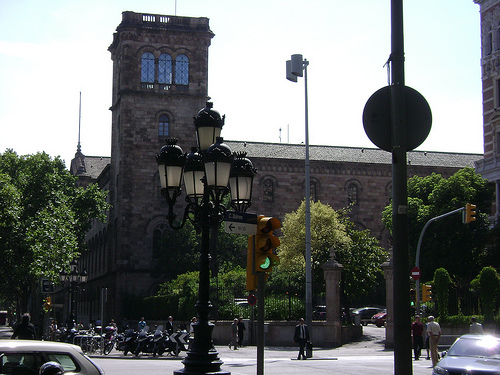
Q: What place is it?
A: It is a town.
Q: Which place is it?
A: It is a town.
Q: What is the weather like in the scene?
A: It is cloudy.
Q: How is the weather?
A: It is cloudy.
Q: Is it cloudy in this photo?
A: Yes, it is cloudy.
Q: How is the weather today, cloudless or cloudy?
A: It is cloudy.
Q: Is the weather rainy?
A: No, it is cloudy.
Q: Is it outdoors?
A: Yes, it is outdoors.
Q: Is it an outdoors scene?
A: Yes, it is outdoors.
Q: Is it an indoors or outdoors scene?
A: It is outdoors.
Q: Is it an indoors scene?
A: No, it is outdoors.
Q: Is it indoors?
A: No, it is outdoors.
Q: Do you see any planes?
A: No, there are no planes.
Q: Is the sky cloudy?
A: Yes, the sky is cloudy.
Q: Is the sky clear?
A: No, the sky is cloudy.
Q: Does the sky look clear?
A: No, the sky is cloudy.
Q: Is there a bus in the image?
A: No, there are no buses.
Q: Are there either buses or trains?
A: No, there are no buses or trains.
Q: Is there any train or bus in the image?
A: No, there are no buses or trains.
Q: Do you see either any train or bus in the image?
A: No, there are no buses or trains.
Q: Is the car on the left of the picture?
A: Yes, the car is on the left of the image.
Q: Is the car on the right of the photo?
A: No, the car is on the left of the image.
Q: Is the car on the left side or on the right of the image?
A: The car is on the left of the image.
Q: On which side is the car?
A: The car is on the left of the image.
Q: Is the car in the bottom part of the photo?
A: Yes, the car is in the bottom of the image.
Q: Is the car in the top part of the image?
A: No, the car is in the bottom of the image.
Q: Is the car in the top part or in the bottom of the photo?
A: The car is in the bottom of the image.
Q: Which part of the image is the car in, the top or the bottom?
A: The car is in the bottom of the image.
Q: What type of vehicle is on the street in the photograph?
A: The vehicle is a car.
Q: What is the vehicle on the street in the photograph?
A: The vehicle is a car.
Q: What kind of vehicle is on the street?
A: The vehicle is a car.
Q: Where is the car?
A: The car is on the street.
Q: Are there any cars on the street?
A: Yes, there is a car on the street.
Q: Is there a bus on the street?
A: No, there is a car on the street.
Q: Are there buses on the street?
A: No, there is a car on the street.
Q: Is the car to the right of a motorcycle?
A: No, the car is to the left of a motorcycle.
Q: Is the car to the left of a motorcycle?
A: Yes, the car is to the left of a motorcycle.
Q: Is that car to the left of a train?
A: No, the car is to the left of a motorcycle.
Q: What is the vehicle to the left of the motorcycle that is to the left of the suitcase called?
A: The vehicle is a car.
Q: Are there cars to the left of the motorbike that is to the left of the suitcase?
A: Yes, there is a car to the left of the motorbike.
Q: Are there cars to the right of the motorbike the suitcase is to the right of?
A: No, the car is to the left of the motorbike.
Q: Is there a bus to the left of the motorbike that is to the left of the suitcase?
A: No, there is a car to the left of the motorcycle.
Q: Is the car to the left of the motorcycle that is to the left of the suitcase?
A: Yes, the car is to the left of the motorbike.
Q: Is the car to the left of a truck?
A: No, the car is to the left of the motorbike.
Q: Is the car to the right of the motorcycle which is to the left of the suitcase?
A: No, the car is to the left of the motorbike.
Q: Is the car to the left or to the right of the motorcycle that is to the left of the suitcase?
A: The car is to the left of the motorbike.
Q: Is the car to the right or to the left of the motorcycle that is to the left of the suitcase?
A: The car is to the left of the motorbike.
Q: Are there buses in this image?
A: No, there are no buses.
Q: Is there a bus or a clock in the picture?
A: No, there are no buses or clocks.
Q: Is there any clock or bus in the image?
A: No, there are no buses or clocks.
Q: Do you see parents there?
A: No, there are no parents.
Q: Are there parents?
A: No, there are no parents.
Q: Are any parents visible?
A: No, there are no parents.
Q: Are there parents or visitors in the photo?
A: No, there are no parents or visitors.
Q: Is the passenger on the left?
A: Yes, the passenger is on the left of the image.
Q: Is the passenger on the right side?
A: No, the passenger is on the left of the image.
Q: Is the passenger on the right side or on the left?
A: The passenger is on the left of the image.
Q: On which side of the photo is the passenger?
A: The passenger is on the left of the image.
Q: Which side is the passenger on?
A: The passenger is on the left of the image.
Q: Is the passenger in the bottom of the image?
A: Yes, the passenger is in the bottom of the image.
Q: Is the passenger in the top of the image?
A: No, the passenger is in the bottom of the image.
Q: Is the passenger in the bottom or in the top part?
A: The passenger is in the bottom of the image.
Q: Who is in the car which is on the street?
A: The passenger is in the car.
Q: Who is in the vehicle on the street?
A: The passenger is in the car.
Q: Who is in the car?
A: The passenger is in the car.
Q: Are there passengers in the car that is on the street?
A: Yes, there is a passenger in the car.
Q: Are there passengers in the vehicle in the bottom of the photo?
A: Yes, there is a passenger in the car.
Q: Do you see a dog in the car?
A: No, there is a passenger in the car.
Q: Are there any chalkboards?
A: No, there are no chalkboards.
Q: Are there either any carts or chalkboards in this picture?
A: No, there are no chalkboards or carts.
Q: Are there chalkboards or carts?
A: No, there are no chalkboards or carts.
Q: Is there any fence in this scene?
A: Yes, there is a fence.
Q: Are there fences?
A: Yes, there is a fence.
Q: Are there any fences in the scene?
A: Yes, there is a fence.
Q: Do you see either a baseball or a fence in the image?
A: Yes, there is a fence.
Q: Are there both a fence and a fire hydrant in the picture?
A: No, there is a fence but no fire hydrants.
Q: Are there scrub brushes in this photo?
A: No, there are no scrub brushes.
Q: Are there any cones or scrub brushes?
A: No, there are no scrub brushes or cones.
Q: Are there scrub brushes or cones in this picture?
A: No, there are no scrub brushes or cones.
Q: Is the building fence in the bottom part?
A: Yes, the fence is in the bottom of the image.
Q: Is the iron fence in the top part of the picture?
A: No, the fence is in the bottom of the image.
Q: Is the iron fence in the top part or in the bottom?
A: The fence is in the bottom of the image.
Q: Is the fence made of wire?
A: No, the fence is made of iron.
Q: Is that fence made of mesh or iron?
A: The fence is made of iron.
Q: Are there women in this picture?
A: No, there are no women.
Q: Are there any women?
A: No, there are no women.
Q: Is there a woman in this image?
A: No, there are no women.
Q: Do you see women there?
A: No, there are no women.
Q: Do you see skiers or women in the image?
A: No, there are no women or skiers.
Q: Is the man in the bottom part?
A: Yes, the man is in the bottom of the image.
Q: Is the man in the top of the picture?
A: No, the man is in the bottom of the image.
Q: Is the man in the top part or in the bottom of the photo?
A: The man is in the bottom of the image.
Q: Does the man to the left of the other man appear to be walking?
A: Yes, the man is walking.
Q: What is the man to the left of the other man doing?
A: The man is walking.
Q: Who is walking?
A: The man is walking.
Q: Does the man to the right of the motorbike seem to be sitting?
A: No, the man is walking.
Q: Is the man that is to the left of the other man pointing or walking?
A: The man is walking.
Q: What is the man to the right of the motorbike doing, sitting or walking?
A: The man is walking.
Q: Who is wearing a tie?
A: The man is wearing a tie.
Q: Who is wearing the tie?
A: The man is wearing a tie.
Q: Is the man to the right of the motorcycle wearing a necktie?
A: Yes, the man is wearing a necktie.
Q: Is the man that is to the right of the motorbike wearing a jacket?
A: No, the man is wearing a necktie.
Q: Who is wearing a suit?
A: The man is wearing a suit.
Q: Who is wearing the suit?
A: The man is wearing a suit.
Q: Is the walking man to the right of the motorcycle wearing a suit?
A: Yes, the man is wearing a suit.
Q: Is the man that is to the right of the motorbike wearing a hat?
A: No, the man is wearing a suit.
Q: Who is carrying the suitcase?
A: The man is carrying the suitcase.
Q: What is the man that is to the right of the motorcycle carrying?
A: The man is carrying a suitcase.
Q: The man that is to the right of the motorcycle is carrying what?
A: The man is carrying a suitcase.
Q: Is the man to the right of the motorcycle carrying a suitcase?
A: Yes, the man is carrying a suitcase.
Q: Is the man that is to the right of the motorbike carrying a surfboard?
A: No, the man is carrying a suitcase.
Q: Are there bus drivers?
A: No, there are no bus drivers.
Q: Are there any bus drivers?
A: No, there are no bus drivers.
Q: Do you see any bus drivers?
A: No, there are no bus drivers.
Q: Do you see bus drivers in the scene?
A: No, there are no bus drivers.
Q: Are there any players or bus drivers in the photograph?
A: No, there are no bus drivers or players.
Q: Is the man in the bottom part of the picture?
A: Yes, the man is in the bottom of the image.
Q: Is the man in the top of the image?
A: No, the man is in the bottom of the image.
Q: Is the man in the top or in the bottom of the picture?
A: The man is in the bottom of the image.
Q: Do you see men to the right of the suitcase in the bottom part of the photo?
A: Yes, there is a man to the right of the suitcase.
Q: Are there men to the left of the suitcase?
A: No, the man is to the right of the suitcase.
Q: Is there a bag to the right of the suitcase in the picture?
A: No, there is a man to the right of the suitcase.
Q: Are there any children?
A: No, there are no children.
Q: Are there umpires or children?
A: No, there are no children or umpires.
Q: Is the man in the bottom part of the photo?
A: Yes, the man is in the bottom of the image.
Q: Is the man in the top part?
A: No, the man is in the bottom of the image.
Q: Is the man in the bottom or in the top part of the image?
A: The man is in the bottom of the image.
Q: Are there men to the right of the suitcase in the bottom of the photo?
A: Yes, there is a man to the right of the suitcase.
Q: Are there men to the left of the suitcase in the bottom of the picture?
A: No, the man is to the right of the suitcase.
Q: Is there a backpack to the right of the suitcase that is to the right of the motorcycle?
A: No, there is a man to the right of the suitcase.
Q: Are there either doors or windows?
A: Yes, there is a window.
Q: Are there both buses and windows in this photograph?
A: No, there is a window but no buses.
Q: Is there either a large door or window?
A: Yes, there is a large window.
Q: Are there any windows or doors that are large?
A: Yes, the window is large.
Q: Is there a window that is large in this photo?
A: Yes, there is a large window.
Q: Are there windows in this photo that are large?
A: Yes, there is a window that is large.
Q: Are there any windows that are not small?
A: Yes, there is a large window.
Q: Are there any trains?
A: No, there are no trains.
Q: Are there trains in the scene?
A: No, there are no trains.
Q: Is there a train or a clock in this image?
A: No, there are no trains or clocks.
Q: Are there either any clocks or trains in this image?
A: No, there are no trains or clocks.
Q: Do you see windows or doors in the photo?
A: Yes, there is a window.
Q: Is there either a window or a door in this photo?
A: Yes, there is a window.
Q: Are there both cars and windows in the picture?
A: Yes, there are both a window and a car.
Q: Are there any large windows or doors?
A: Yes, there is a large window.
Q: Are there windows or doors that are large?
A: Yes, the window is large.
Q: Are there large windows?
A: Yes, there is a large window.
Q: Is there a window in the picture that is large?
A: Yes, there is a window that is large.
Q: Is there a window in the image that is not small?
A: Yes, there is a large window.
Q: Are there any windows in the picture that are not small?
A: Yes, there is a large window.